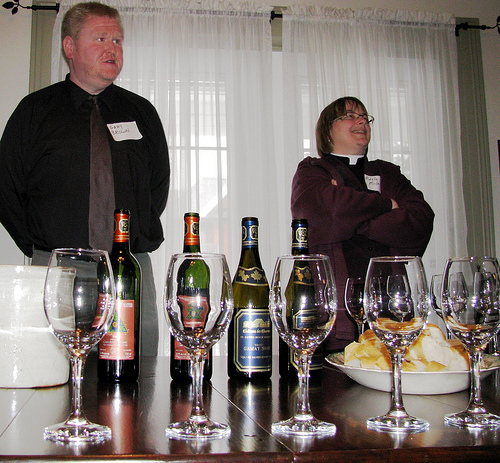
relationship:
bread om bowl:
[358, 340, 444, 365] [329, 365, 499, 392]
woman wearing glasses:
[293, 89, 442, 264] [336, 109, 385, 124]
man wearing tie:
[15, 6, 167, 275] [89, 99, 122, 251]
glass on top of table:
[53, 245, 109, 452] [9, 373, 490, 457]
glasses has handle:
[34, 248, 499, 447] [186, 362, 208, 413]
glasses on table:
[34, 248, 499, 447] [9, 373, 490, 457]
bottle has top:
[231, 212, 276, 381] [244, 217, 259, 232]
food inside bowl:
[350, 325, 478, 373] [329, 365, 499, 392]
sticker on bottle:
[237, 309, 284, 372] [231, 212, 276, 381]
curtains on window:
[135, 13, 412, 197] [63, 18, 490, 189]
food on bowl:
[350, 325, 478, 373] [329, 365, 499, 392]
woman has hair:
[293, 89, 442, 264] [313, 110, 335, 155]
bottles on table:
[95, 210, 328, 383] [9, 373, 490, 457]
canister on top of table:
[6, 263, 71, 395] [9, 373, 490, 457]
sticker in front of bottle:
[237, 309, 284, 372] [231, 212, 276, 381]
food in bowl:
[350, 325, 478, 373] [329, 365, 499, 392]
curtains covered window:
[135, 13, 412, 197] [63, 18, 490, 189]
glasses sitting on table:
[34, 248, 499, 447] [9, 373, 490, 457]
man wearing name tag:
[15, 6, 167, 275] [108, 126, 145, 148]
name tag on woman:
[358, 176, 391, 198] [293, 89, 442, 264]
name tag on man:
[108, 126, 145, 148] [15, 6, 167, 275]